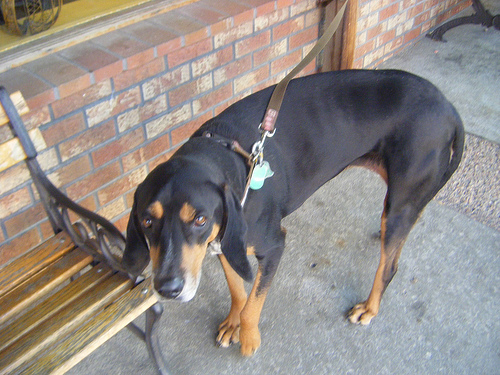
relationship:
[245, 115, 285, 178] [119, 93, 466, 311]
leash on dog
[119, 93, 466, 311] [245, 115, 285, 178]
dog on leash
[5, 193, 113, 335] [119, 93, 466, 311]
bench near dog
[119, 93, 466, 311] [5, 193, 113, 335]
dog near bench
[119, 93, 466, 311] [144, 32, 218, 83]
dog near wall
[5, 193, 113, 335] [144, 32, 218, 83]
bench near wall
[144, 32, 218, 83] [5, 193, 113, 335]
wall near bench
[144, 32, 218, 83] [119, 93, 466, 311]
wall above dog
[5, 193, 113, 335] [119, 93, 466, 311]
bench by dog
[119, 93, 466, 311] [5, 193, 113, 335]
dog by bench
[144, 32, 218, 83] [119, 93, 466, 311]
wall by dog